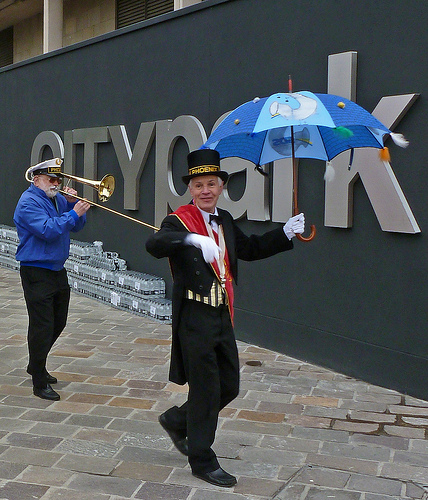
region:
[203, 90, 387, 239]
A blue umbrella in the man's hand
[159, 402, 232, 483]
The man is wearing black shoes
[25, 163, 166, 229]
The man is playing a trombone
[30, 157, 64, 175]
The man is wearing a hat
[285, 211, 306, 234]
A glove on the man's left had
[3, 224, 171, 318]
Bottles of water behind the trombone player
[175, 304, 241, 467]
The man is wearing black pants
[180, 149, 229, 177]
The man is wearing a top hat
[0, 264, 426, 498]
The ground is made of bricks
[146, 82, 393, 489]
A fancy man holding an umbrella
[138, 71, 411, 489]
an old man with a top hat carrying an umbrella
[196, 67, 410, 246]
a blue umbrella in the man's left hand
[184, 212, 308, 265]
white gloves on the man's hands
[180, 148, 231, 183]
a top hat on the man's head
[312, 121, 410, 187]
small feathers coming off of the umbrella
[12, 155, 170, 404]
a man playing a trombone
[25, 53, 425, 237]
a large sign that says Citypark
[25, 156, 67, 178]
a sailor's hat on the man's head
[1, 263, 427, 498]
a walkway made of brick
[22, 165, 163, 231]
a trombone in the man's hands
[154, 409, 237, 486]
Man is wearing shoes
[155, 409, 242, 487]
Man is wearing black shoes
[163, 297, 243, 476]
Man is wearing pants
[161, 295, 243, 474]
Man is wearing black pants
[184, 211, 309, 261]
Man is wearing gloves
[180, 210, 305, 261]
Man is wearing white gloves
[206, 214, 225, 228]
Man is wearing a bow tie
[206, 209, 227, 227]
Man is wearing a black bow tie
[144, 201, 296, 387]
Man is wearing a coat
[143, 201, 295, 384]
Man is wearing a black coat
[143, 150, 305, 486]
man walking down the street with an umbrella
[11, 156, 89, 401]
man playing a trombone on the street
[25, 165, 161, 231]
a brass trombone being played by the man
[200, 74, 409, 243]
a blue umbrella in the man's hand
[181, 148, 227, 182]
a black top hat on the man's head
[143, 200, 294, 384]
a black coat on the man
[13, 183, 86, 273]
blue jacket on the man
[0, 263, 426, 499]
a sidewalk paved with bricks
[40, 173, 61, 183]
sunglasses on the man's face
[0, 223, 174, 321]
bottles of water stacked against the wall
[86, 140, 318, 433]
man on the cement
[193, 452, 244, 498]
shoe on man's foot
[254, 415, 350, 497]
brick ground under man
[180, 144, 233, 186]
hat on man's head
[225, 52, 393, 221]
blue umbrella in man's hand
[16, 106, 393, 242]
letters on a large sign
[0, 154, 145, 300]
man playing an instrument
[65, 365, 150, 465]
many different colored bricks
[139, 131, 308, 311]
man looking near the camera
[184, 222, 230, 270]
white glove on man's hand